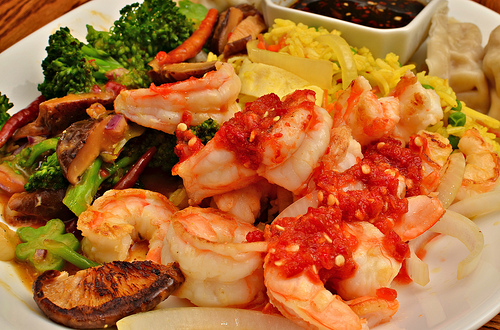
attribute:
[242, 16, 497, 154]
rice — yellow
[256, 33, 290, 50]
carrot — small, orange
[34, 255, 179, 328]
wedge — burnt , small,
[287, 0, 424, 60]
sauce — thick, spicy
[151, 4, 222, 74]
carrot — small, thin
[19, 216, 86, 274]
vegetable piece — green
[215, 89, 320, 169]
marinara sauce — Marinara 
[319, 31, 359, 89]
onion — white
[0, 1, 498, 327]
plate — white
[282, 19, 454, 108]
rice — Fried 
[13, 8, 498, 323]
bowl — white, square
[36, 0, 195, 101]
sauted broccoli — sauted 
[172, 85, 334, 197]
shrimp — piece ,  large 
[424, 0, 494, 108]
wontons — cooked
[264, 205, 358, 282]
sauce — red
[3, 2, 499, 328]
dish — delicious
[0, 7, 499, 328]
meal — Asian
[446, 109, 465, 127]
pea — small, green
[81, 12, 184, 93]
broccoli — green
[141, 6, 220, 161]
carrots — orange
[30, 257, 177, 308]
meat — black, brown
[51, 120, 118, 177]
mushroom — brown, Piece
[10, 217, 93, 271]
green vegetable — shaped, star 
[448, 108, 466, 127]
pea — green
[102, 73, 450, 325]
shrimp — large, pink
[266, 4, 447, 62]
bowl. — corner